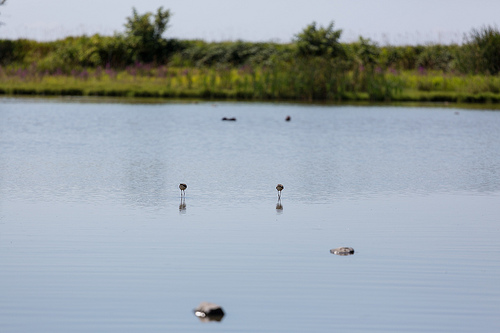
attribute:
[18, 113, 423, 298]
lake — still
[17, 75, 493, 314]
lake — still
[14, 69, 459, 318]
lake — still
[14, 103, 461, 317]
lake — still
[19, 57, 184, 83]
flowers — purple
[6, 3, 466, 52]
skies — gray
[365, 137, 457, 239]
body — large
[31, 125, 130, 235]
body — large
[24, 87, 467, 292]
water — blue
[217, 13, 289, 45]
body — large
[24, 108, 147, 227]
area — large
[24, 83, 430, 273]
water — blue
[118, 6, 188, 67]
tree — large, green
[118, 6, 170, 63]
tree — large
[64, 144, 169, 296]
pond — blue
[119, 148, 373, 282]
ducks — light gray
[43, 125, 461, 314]
water — calm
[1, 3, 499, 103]
plants — green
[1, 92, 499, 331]
water — calm, blue, dark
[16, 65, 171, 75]
flowers — purple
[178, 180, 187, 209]
buoy — dark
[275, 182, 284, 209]
buoy — dark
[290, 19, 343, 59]
trees — brown, green leafed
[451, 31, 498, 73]
trees — brown, green leafed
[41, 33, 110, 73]
trees — green leafed, brown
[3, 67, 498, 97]
grass — tall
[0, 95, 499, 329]
lake — blue, water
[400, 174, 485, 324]
water — blue